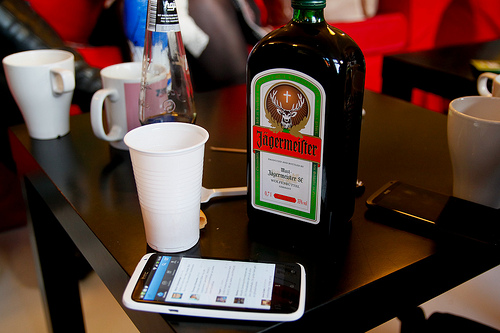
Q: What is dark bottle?
A: Liquor.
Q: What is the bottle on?
A: Table.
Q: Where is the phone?
A: Table.